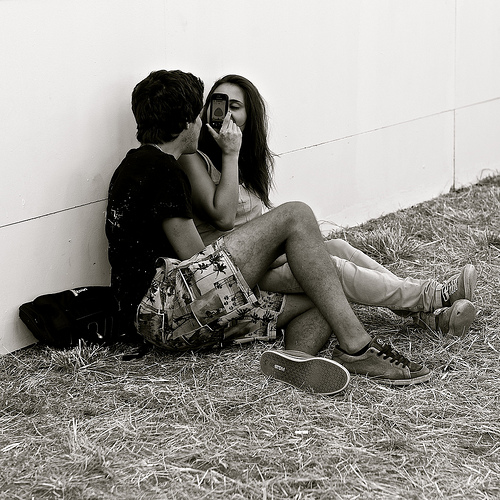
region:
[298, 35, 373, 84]
part of a wall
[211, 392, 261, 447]
part of some grass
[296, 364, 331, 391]
sole of ashoe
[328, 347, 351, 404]
edge of a shoe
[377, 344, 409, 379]
part of some laces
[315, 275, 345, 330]
part of a leg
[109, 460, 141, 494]
part of a ground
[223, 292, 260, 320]
part of a short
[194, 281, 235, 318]
part of a short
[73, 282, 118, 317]
part of a bag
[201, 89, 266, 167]
Woman holding cell phone.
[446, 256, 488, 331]
Woman wearing tennis shoes.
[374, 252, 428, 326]
Woman wearing light colored pants.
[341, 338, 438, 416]
Man wearing tennis shoes.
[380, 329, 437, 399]
Tennis shoes have dark laces.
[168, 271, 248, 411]
Man wearing shorts with pattern.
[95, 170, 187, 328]
Man wearing black shirt.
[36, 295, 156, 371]
Black bag behind man.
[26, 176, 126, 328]
People leaning against white wall.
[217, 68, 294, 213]
Woman has long dark hair.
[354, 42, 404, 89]
part of a wall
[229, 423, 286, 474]
part of some dry grass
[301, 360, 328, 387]
sole of a shoe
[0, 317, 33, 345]
part of a wall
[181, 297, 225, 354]
part of a short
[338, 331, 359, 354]
part of a leg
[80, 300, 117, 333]
part of a bag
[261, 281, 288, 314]
edge of a short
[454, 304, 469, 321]
sole of a shoe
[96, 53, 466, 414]
young couple sitting on the grass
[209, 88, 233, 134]
phone held in fron of womans face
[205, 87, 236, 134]
phone in womans right hand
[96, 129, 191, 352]
young man wearing a black shirt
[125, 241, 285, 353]
young man wearing shorts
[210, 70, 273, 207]
young girl has long hair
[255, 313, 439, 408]
young man with no socks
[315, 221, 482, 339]
long pants worn by the woman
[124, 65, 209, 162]
young man facing the phone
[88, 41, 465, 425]
couple taking photos with phone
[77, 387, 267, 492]
this is some grass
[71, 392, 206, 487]
the grass is cut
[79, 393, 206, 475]
the grass is short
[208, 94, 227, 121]
this is a mobile phone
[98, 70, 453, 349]
these are two people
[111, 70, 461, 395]
the people are seated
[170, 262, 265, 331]
this is a pair of shorts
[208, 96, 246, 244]
the woman is holding the mobile phone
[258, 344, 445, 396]
this is a pair of shoes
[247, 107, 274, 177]
the hair is long